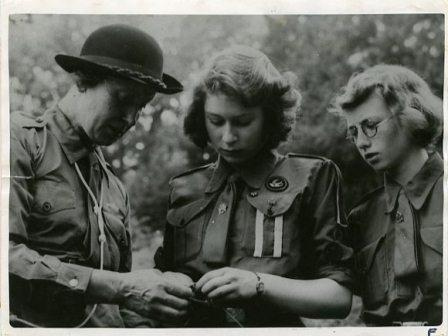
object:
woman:
[142, 46, 356, 329]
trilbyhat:
[50, 21, 186, 95]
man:
[7, 24, 193, 323]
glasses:
[342, 114, 396, 142]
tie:
[199, 169, 246, 266]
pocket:
[164, 197, 209, 264]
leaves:
[318, 50, 324, 60]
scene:
[6, 11, 441, 326]